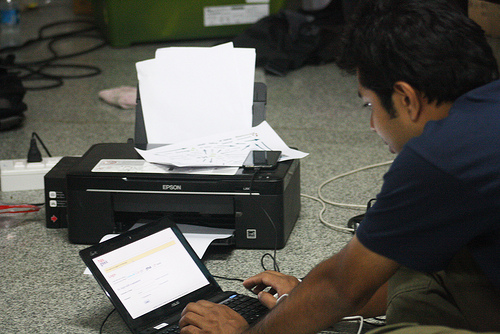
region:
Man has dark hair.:
[427, 60, 442, 75]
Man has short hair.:
[416, 66, 475, 95]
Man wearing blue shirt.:
[398, 153, 450, 228]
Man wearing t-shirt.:
[415, 163, 452, 228]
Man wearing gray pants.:
[391, 276, 446, 321]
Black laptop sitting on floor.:
[113, 248, 188, 320]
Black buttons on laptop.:
[237, 291, 258, 324]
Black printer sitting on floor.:
[71, 155, 228, 252]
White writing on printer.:
[156, 179, 191, 198]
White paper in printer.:
[146, 75, 236, 139]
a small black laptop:
[78, 215, 268, 332]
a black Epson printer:
[42, 144, 301, 218]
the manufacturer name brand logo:
[161, 181, 183, 192]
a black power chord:
[26, 132, 50, 164]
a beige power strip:
[0, 158, 49, 190]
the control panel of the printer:
[44, 185, 64, 227]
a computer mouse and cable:
[301, 164, 363, 234]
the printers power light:
[49, 212, 59, 224]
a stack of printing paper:
[133, 43, 254, 146]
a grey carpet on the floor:
[3, 226, 68, 333]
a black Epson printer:
[38, 33, 313, 245]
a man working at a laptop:
[107, 19, 477, 323]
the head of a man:
[352, 13, 494, 163]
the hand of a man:
[235, 269, 302, 307]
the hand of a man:
[180, 294, 251, 331]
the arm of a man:
[268, 241, 401, 326]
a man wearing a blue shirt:
[341, 6, 494, 273]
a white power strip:
[0, 123, 49, 194]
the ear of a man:
[387, 75, 424, 120]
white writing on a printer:
[157, 181, 189, 196]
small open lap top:
[84, 226, 232, 331]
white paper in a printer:
[132, 32, 249, 120]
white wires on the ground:
[307, 146, 368, 228]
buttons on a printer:
[48, 182, 61, 225]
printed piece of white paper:
[159, 135, 246, 163]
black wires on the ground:
[249, 218, 285, 278]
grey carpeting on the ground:
[310, 96, 349, 163]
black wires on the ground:
[37, 32, 72, 77]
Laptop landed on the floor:
[71, 226, 313, 329]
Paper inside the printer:
[121, 45, 266, 148]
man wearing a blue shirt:
[378, 124, 496, 251]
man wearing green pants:
[383, 274, 496, 332]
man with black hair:
[321, 9, 490, 119]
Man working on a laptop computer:
[168, 269, 303, 324]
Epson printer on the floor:
[48, 100, 298, 252]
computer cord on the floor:
[311, 154, 370, 242]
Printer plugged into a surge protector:
[14, 125, 57, 163]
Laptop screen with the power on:
[71, 221, 219, 303]